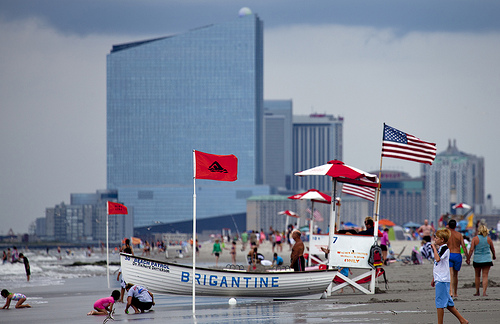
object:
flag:
[192, 148, 238, 317]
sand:
[1, 239, 500, 324]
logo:
[207, 160, 228, 173]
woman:
[465, 223, 498, 296]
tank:
[472, 234, 493, 263]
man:
[445, 219, 470, 298]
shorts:
[449, 253, 462, 272]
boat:
[119, 252, 338, 300]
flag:
[381, 123, 438, 166]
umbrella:
[294, 158, 383, 300]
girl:
[84, 290, 120, 317]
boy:
[430, 229, 470, 324]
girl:
[1, 288, 32, 309]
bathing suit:
[10, 293, 26, 301]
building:
[105, 6, 266, 237]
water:
[0, 247, 426, 324]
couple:
[448, 219, 499, 297]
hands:
[465, 259, 471, 265]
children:
[1, 283, 156, 315]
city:
[1, 0, 500, 248]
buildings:
[30, 7, 498, 234]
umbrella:
[277, 209, 300, 244]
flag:
[105, 200, 128, 288]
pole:
[191, 150, 197, 324]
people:
[1, 210, 500, 324]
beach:
[0, 237, 499, 324]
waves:
[1, 252, 121, 277]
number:
[333, 237, 338, 244]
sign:
[329, 234, 374, 270]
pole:
[374, 123, 386, 238]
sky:
[0, 0, 500, 236]